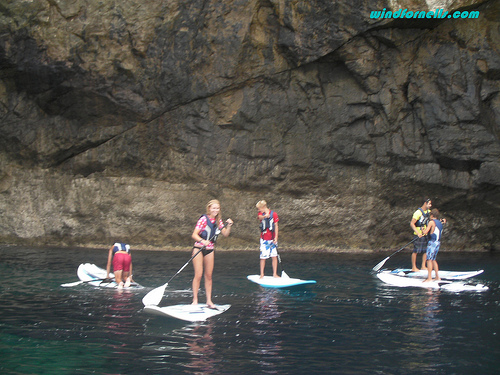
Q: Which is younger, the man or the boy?
A: The boy is younger than the man.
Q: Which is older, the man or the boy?
A: The man is older than the boy.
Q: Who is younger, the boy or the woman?
A: The boy is younger than the woman.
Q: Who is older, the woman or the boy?
A: The woman is older than the boy.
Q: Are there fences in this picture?
A: No, there are no fences.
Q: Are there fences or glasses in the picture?
A: No, there are no fences or glasses.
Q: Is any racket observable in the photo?
A: No, there are no rackets.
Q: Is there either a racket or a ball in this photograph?
A: No, there are no rackets or balls.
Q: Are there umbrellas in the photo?
A: No, there are no umbrellas.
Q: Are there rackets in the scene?
A: No, there are no rackets.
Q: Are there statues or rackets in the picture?
A: No, there are no rackets or statues.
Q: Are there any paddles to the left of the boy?
A: Yes, there is a paddle to the left of the boy.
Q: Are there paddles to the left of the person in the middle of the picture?
A: Yes, there is a paddle to the left of the boy.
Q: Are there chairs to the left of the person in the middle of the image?
A: No, there is a paddle to the left of the boy.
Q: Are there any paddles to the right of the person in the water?
A: Yes, there is a paddle to the right of the person.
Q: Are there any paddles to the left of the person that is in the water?
A: No, the paddle is to the right of the person.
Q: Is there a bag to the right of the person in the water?
A: No, there is a paddle to the right of the person.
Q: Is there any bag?
A: No, there are no bags.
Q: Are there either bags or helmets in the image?
A: No, there are no bags or helmets.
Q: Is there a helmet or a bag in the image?
A: No, there are no bags or helmets.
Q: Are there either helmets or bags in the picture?
A: No, there are no bags or helmets.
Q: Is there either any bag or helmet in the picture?
A: No, there are no bags or helmets.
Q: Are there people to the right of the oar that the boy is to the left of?
A: Yes, there is a person to the right of the oar.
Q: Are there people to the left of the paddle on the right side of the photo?
A: No, the person is to the right of the oar.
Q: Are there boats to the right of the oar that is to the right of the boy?
A: No, there is a person to the right of the paddle.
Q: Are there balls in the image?
A: No, there are no balls.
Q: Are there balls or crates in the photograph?
A: No, there are no balls or crates.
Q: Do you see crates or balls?
A: No, there are no balls or crates.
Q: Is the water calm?
A: Yes, the water is calm.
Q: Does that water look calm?
A: Yes, the water is calm.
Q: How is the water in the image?
A: The water is calm.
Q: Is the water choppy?
A: No, the water is calm.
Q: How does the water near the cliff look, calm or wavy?
A: The water is calm.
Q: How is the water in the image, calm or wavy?
A: The water is calm.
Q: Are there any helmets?
A: No, there are no helmets.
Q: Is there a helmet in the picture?
A: No, there are no helmets.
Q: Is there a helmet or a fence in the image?
A: No, there are no helmets or fences.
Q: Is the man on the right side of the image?
A: Yes, the man is on the right of the image.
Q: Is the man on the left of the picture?
A: No, the man is on the right of the image.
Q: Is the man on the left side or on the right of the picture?
A: The man is on the right of the image.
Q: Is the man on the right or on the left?
A: The man is on the right of the image.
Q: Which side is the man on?
A: The man is on the right of the image.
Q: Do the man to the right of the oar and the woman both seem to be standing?
A: Yes, both the man and the woman are standing.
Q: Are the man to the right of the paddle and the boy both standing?
A: Yes, both the man and the boy are standing.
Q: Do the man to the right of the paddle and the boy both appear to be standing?
A: Yes, both the man and the boy are standing.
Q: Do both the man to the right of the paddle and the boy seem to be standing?
A: Yes, both the man and the boy are standing.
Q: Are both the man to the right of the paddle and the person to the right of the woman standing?
A: Yes, both the man and the boy are standing.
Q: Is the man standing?
A: Yes, the man is standing.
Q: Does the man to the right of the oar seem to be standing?
A: Yes, the man is standing.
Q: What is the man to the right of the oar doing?
A: The man is standing.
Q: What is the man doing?
A: The man is standing.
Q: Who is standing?
A: The man is standing.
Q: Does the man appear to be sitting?
A: No, the man is standing.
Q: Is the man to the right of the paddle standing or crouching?
A: The man is standing.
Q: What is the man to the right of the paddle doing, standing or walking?
A: The man is standing.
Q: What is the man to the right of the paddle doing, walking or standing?
A: The man is standing.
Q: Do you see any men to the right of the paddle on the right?
A: Yes, there is a man to the right of the oar.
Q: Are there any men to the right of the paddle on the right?
A: Yes, there is a man to the right of the oar.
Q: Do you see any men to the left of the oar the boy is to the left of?
A: No, the man is to the right of the paddle.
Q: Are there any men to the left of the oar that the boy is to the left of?
A: No, the man is to the right of the paddle.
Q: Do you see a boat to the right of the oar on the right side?
A: No, there is a man to the right of the oar.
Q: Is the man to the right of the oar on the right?
A: Yes, the man is to the right of the paddle.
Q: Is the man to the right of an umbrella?
A: No, the man is to the right of the paddle.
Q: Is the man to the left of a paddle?
A: No, the man is to the right of a paddle.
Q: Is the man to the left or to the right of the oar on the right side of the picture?
A: The man is to the right of the oar.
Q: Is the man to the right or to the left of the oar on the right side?
A: The man is to the right of the oar.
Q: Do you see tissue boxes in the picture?
A: No, there are no tissue boxes.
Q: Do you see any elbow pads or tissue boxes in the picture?
A: No, there are no tissue boxes or elbow pads.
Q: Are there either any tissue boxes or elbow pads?
A: No, there are no tissue boxes or elbow pads.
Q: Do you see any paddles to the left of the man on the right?
A: Yes, there is a paddle to the left of the man.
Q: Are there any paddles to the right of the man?
A: No, the paddle is to the left of the man.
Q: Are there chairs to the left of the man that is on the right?
A: No, there is a paddle to the left of the man.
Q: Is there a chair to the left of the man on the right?
A: No, there is a paddle to the left of the man.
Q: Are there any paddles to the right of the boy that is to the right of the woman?
A: Yes, there is a paddle to the right of the boy.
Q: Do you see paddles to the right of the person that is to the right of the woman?
A: Yes, there is a paddle to the right of the boy.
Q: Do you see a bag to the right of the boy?
A: No, there is a paddle to the right of the boy.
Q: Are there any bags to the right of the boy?
A: No, there is a paddle to the right of the boy.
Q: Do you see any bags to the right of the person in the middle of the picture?
A: No, there is a paddle to the right of the boy.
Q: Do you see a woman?
A: Yes, there is a woman.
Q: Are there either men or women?
A: Yes, there is a woman.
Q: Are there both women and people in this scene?
A: Yes, there are both a woman and people.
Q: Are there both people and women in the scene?
A: Yes, there are both a woman and people.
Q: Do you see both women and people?
A: Yes, there are both a woman and people.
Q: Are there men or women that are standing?
A: Yes, the woman is standing.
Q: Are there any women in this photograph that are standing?
A: Yes, there is a woman that is standing.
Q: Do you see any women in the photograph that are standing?
A: Yes, there is a woman that is standing.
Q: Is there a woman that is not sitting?
A: Yes, there is a woman that is standing.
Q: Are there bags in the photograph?
A: No, there are no bags.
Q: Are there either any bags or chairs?
A: No, there are no bags or chairs.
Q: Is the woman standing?
A: Yes, the woman is standing.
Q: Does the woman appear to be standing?
A: Yes, the woman is standing.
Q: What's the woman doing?
A: The woman is standing.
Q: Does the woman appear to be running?
A: No, the woman is standing.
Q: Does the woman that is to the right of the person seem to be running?
A: No, the woman is standing.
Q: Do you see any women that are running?
A: No, there is a woman but she is standing.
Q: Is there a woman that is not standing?
A: No, there is a woman but she is standing.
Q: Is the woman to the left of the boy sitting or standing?
A: The woman is standing.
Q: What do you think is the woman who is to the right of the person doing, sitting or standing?
A: The woman is standing.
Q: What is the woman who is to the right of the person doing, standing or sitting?
A: The woman is standing.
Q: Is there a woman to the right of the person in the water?
A: Yes, there is a woman to the right of the person.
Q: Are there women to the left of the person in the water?
A: No, the woman is to the right of the person.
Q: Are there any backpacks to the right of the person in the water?
A: No, there is a woman to the right of the person.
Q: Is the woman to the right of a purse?
A: No, the woman is to the right of a person.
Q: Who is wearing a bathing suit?
A: The woman is wearing a bathing suit.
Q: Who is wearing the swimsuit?
A: The woman is wearing a bathing suit.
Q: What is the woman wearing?
A: The woman is wearing a bathing suit.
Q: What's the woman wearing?
A: The woman is wearing a bathing suit.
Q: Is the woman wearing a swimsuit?
A: Yes, the woman is wearing a swimsuit.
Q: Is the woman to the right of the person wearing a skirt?
A: No, the woman is wearing a swimsuit.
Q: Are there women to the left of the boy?
A: Yes, there is a woman to the left of the boy.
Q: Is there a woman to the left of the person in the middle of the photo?
A: Yes, there is a woman to the left of the boy.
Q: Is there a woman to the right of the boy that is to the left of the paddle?
A: No, the woman is to the left of the boy.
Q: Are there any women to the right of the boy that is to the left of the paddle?
A: No, the woman is to the left of the boy.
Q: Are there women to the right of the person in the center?
A: No, the woman is to the left of the boy.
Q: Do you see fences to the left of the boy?
A: No, there is a woman to the left of the boy.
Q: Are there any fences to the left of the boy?
A: No, there is a woman to the left of the boy.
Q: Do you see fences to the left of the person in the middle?
A: No, there is a woman to the left of the boy.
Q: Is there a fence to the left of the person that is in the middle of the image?
A: No, there is a woman to the left of the boy.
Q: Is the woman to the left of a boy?
A: Yes, the woman is to the left of a boy.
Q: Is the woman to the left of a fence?
A: No, the woman is to the left of a boy.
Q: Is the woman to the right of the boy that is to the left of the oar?
A: No, the woman is to the left of the boy.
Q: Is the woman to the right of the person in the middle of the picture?
A: No, the woman is to the left of the boy.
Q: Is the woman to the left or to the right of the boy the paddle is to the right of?
A: The woman is to the left of the boy.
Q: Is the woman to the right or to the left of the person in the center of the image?
A: The woman is to the left of the boy.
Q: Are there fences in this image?
A: No, there are no fences.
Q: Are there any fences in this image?
A: No, there are no fences.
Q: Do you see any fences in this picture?
A: No, there are no fences.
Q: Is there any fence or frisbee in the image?
A: No, there are no fences or frisbees.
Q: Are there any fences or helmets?
A: No, there are no helmets or fences.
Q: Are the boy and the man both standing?
A: Yes, both the boy and the man are standing.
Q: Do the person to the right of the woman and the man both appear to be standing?
A: Yes, both the boy and the man are standing.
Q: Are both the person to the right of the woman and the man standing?
A: Yes, both the boy and the man are standing.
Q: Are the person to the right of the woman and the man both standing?
A: Yes, both the boy and the man are standing.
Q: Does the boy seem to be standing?
A: Yes, the boy is standing.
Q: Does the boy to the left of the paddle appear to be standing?
A: Yes, the boy is standing.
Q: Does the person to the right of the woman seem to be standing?
A: Yes, the boy is standing.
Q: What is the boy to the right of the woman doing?
A: The boy is standing.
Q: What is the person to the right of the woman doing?
A: The boy is standing.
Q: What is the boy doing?
A: The boy is standing.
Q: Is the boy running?
A: No, the boy is standing.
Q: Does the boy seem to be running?
A: No, the boy is standing.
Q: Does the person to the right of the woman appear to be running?
A: No, the boy is standing.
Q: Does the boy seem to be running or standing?
A: The boy is standing.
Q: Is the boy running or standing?
A: The boy is standing.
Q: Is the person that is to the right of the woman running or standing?
A: The boy is standing.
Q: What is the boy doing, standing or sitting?
A: The boy is standing.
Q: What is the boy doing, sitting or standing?
A: The boy is standing.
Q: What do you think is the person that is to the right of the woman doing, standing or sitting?
A: The boy is standing.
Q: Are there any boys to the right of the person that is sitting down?
A: Yes, there is a boy to the right of the person.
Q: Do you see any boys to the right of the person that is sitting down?
A: Yes, there is a boy to the right of the person.